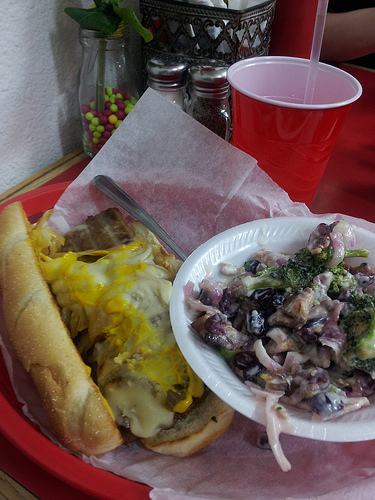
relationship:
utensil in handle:
[89, 173, 190, 261] [86, 172, 192, 272]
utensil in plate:
[89, 173, 190, 261] [2, 179, 374, 497]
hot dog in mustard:
[2, 193, 219, 462] [45, 249, 165, 346]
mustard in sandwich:
[68, 257, 132, 306] [0, 197, 235, 462]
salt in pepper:
[147, 55, 188, 109] [189, 63, 232, 139]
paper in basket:
[35, 89, 375, 500] [0, 180, 342, 498]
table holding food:
[340, 105, 370, 194] [2, 203, 370, 455]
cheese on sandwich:
[121, 386, 146, 431] [0, 197, 235, 462]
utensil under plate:
[89, 173, 190, 261] [169, 215, 373, 442]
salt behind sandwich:
[147, 55, 188, 109] [0, 197, 235, 462]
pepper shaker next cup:
[182, 54, 238, 145] [219, 53, 361, 221]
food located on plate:
[0, 197, 375, 454] [2, 179, 374, 497]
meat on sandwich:
[47, 204, 210, 431] [0, 197, 235, 462]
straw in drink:
[299, 0, 332, 107] [224, 55, 362, 209]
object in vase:
[107, 101, 118, 112] [73, 23, 149, 162]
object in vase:
[81, 91, 131, 149] [73, 23, 149, 162]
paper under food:
[97, 92, 238, 210] [2, 203, 370, 455]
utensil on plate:
[89, 173, 190, 261] [0, 172, 300, 266]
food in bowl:
[168, 256, 361, 391] [168, 208, 373, 452]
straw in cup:
[294, 9, 351, 114] [226, 53, 362, 207]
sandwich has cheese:
[0, 197, 235, 462] [57, 245, 132, 316]